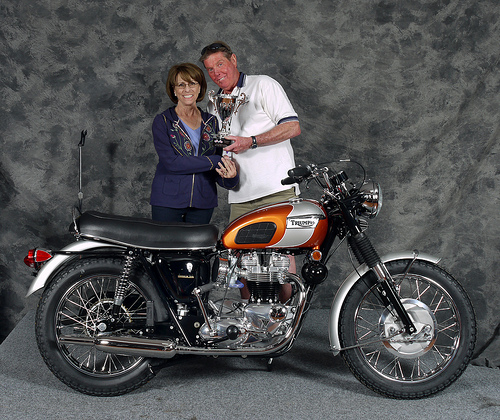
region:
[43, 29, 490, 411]
People by the motorcycle.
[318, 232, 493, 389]
Wheel on the motorcycle.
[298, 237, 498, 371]
Spokes on the wheel.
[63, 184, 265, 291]
Seat on the bike.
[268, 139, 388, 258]
Handles on the bike.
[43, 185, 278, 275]
Leather seat on the bike.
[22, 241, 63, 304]
Light on the bike.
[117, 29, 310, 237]
Two people by the bike.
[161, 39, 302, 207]
People holding a trophy.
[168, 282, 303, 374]
Pedal on the bike.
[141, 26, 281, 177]
coupld holding a trophy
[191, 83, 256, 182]
the trophy is silver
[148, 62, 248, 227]
Woman posing with trophy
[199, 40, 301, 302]
Man posing with trophy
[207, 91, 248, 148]
Award trophy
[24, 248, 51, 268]
back motorcycle brake light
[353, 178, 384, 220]
Front motorcycle head light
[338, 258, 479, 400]
Front wheel of motorcycle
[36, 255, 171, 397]
Back wheel of motorcycle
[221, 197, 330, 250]
orange and silver gas tank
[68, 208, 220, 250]
Black leather motorcycle seat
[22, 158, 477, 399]
orange silver and black motorcycle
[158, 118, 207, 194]
woman is blue jacket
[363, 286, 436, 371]
chrome front wheel on motorbike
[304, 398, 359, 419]
motor bike on gray carpet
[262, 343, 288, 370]
chrome kick stand on motorbike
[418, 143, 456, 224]
gray back drop behind couple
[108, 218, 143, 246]
black seat of motorbike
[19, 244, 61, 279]
red brake light of motorbike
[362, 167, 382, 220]
chrome head lamp of motorbike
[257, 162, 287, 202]
man wearing white shirt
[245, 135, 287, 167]
man wearing black watch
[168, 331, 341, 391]
A shadow on the ground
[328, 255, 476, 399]
The front tire of the motorcycle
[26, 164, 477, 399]
A motorcycle near the people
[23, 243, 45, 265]
The tail light of the motorcycle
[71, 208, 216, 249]
The black seat of the motorcycle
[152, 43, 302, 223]
People standing near the motorcycle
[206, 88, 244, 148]
The man is holding a trophy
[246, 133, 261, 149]
The man has a watch on his left hand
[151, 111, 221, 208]
The woman is wearing a blue sweatshirt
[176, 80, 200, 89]
The woman is wearing glasses